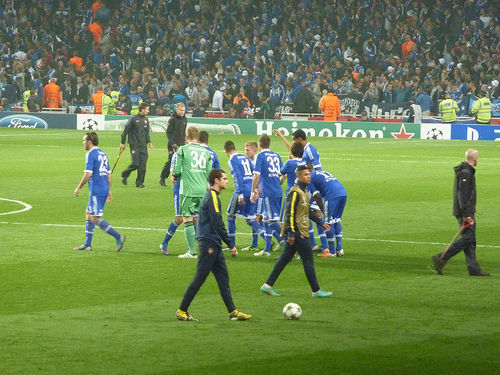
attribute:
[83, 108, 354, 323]
players — wearing blue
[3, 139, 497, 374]
field — green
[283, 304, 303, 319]
ball — white, round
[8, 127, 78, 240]
turf — green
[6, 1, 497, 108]
spectators — watching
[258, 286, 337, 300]
shoes — green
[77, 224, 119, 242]
socks — blue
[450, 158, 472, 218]
jacket — dark, black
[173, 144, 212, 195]
jersey — green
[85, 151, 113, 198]
jersey — blue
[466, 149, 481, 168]
head — bald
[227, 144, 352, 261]
uniforms — blue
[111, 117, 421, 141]
sign — green, on wall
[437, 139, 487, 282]
man — walking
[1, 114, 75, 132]
sign — in background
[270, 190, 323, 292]
outfit — black, yellow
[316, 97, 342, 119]
suit — orange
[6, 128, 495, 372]
grass — green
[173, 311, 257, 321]
shoes — yellow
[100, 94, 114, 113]
jacket — yellow